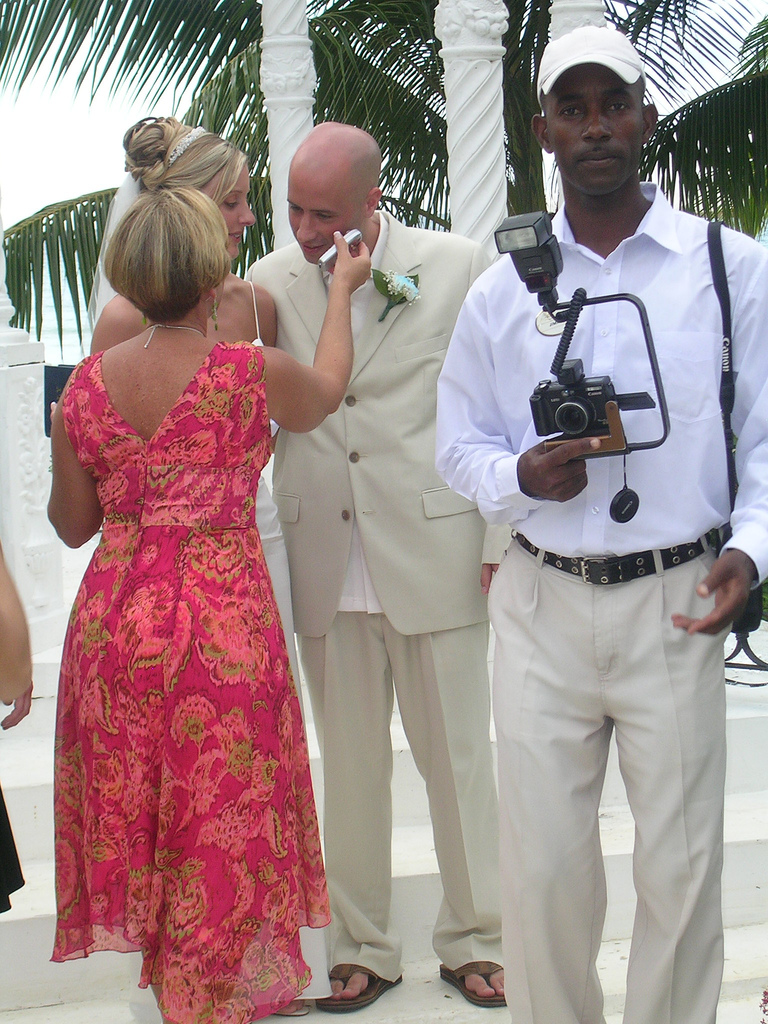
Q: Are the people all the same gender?
A: No, they are both male and female.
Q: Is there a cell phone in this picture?
A: Yes, there is a cell phone.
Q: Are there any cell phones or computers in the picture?
A: Yes, there is a cell phone.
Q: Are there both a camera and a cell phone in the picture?
A: Yes, there are both a cell phone and a camera.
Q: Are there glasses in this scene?
A: No, there are no glasses.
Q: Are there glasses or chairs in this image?
A: No, there are no glasses or chairs.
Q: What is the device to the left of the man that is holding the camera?
A: The device is a cell phone.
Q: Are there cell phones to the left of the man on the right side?
A: Yes, there is a cell phone to the left of the man.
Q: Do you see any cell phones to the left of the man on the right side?
A: Yes, there is a cell phone to the left of the man.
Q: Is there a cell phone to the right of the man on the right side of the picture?
A: No, the cell phone is to the left of the man.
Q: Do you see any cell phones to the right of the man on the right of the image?
A: No, the cell phone is to the left of the man.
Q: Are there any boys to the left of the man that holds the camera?
A: No, there is a cell phone to the left of the man.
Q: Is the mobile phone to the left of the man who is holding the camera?
A: Yes, the mobile phone is to the left of the man.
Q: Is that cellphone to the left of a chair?
A: No, the cellphone is to the left of the man.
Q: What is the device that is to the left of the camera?
A: The device is a cell phone.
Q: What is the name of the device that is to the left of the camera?
A: The device is a cell phone.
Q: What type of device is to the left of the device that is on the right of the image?
A: The device is a cell phone.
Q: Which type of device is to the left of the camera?
A: The device is a cell phone.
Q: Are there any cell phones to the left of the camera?
A: Yes, there is a cell phone to the left of the camera.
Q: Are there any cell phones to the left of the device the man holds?
A: Yes, there is a cell phone to the left of the camera.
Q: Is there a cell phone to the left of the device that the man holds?
A: Yes, there is a cell phone to the left of the camera.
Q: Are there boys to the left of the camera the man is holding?
A: No, there is a cell phone to the left of the camera.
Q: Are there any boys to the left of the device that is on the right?
A: No, there is a cell phone to the left of the camera.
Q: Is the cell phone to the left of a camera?
A: Yes, the cell phone is to the left of a camera.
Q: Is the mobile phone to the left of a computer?
A: No, the mobile phone is to the left of a camera.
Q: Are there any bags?
A: No, there are no bags.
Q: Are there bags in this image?
A: No, there are no bags.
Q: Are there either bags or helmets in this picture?
A: No, there are no bags or helmets.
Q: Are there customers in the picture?
A: No, there are no customers.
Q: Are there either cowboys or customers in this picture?
A: No, there are no customers or cowboys.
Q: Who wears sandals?
A: The man wears sandals.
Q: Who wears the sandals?
A: The man wears sandals.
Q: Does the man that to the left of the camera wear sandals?
A: Yes, the man wears sandals.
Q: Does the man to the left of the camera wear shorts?
A: No, the man wears sandals.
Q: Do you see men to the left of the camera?
A: Yes, there is a man to the left of the camera.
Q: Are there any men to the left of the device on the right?
A: Yes, there is a man to the left of the camera.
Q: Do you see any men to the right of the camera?
A: No, the man is to the left of the camera.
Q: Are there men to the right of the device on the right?
A: No, the man is to the left of the camera.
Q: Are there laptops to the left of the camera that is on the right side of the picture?
A: No, there is a man to the left of the camera.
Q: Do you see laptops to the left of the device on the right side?
A: No, there is a man to the left of the camera.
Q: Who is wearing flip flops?
A: The man is wearing flip flops.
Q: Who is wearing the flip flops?
A: The man is wearing flip flops.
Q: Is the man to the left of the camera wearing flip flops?
A: Yes, the man is wearing flip flops.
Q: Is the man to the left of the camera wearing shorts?
A: No, the man is wearing flip flops.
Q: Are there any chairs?
A: No, there are no chairs.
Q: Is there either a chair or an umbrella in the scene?
A: No, there are no chairs or umbrellas.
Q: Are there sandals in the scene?
A: Yes, there are sandals.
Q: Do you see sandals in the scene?
A: Yes, there are sandals.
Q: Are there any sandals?
A: Yes, there are sandals.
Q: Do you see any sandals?
A: Yes, there are sandals.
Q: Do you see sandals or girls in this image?
A: Yes, there are sandals.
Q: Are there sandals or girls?
A: Yes, there are sandals.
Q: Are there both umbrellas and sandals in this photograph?
A: No, there are sandals but no umbrellas.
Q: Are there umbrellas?
A: No, there are no umbrellas.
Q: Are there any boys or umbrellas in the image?
A: No, there are no umbrellas or boys.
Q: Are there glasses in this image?
A: No, there are no glasses.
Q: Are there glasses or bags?
A: No, there are no glasses or bags.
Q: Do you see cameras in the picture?
A: Yes, there is a camera.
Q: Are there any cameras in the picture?
A: Yes, there is a camera.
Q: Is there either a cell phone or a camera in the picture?
A: Yes, there is a camera.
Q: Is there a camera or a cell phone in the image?
A: Yes, there is a camera.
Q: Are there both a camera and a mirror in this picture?
A: No, there is a camera but no mirrors.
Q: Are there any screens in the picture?
A: No, there are no screens.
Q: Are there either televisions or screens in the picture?
A: No, there are no screens or televisions.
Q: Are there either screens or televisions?
A: No, there are no screens or televisions.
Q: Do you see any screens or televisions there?
A: No, there are no screens or televisions.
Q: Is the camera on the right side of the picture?
A: Yes, the camera is on the right of the image.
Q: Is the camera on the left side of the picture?
A: No, the camera is on the right of the image.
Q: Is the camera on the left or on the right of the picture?
A: The camera is on the right of the image.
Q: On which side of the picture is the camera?
A: The camera is on the right of the image.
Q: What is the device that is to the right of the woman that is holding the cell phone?
A: The device is a camera.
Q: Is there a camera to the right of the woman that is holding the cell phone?
A: Yes, there is a camera to the right of the woman.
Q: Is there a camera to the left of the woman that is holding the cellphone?
A: No, the camera is to the right of the woman.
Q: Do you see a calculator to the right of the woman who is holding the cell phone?
A: No, there is a camera to the right of the woman.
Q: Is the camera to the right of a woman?
A: Yes, the camera is to the right of a woman.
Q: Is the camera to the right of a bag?
A: No, the camera is to the right of a woman.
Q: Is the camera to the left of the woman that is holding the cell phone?
A: No, the camera is to the right of the woman.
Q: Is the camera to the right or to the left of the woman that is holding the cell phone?
A: The camera is to the right of the woman.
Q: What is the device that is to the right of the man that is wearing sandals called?
A: The device is a camera.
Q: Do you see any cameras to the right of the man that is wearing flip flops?
A: Yes, there is a camera to the right of the man.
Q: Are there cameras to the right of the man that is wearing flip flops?
A: Yes, there is a camera to the right of the man.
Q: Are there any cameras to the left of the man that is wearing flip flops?
A: No, the camera is to the right of the man.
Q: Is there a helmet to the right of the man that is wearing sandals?
A: No, there is a camera to the right of the man.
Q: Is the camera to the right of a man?
A: Yes, the camera is to the right of a man.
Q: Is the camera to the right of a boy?
A: No, the camera is to the right of a man.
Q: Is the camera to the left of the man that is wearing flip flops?
A: No, the camera is to the right of the man.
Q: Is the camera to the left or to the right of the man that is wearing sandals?
A: The camera is to the right of the man.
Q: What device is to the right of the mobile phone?
A: The device is a camera.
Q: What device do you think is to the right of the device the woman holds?
A: The device is a camera.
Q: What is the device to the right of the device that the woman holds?
A: The device is a camera.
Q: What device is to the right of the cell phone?
A: The device is a camera.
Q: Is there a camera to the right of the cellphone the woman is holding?
A: Yes, there is a camera to the right of the cell phone.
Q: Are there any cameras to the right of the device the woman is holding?
A: Yes, there is a camera to the right of the cell phone.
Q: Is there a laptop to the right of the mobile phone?
A: No, there is a camera to the right of the mobile phone.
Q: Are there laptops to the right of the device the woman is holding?
A: No, there is a camera to the right of the mobile phone.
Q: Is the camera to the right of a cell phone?
A: Yes, the camera is to the right of a cell phone.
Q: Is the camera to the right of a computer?
A: No, the camera is to the right of a cell phone.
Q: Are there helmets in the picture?
A: No, there are no helmets.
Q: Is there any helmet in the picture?
A: No, there are no helmets.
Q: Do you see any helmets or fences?
A: No, there are no helmets or fences.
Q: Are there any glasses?
A: No, there are no glasses.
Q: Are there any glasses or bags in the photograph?
A: No, there are no glasses or bags.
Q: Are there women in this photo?
A: Yes, there is a woman.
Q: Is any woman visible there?
A: Yes, there is a woman.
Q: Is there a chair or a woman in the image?
A: Yes, there is a woman.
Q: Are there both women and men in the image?
A: Yes, there are both a woman and a man.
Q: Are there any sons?
A: No, there are no sons.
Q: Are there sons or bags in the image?
A: No, there are no sons or bags.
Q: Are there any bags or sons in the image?
A: No, there are no sons or bags.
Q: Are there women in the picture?
A: Yes, there is a woman.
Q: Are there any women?
A: Yes, there is a woman.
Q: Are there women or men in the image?
A: Yes, there is a woman.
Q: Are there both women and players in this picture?
A: No, there is a woman but no players.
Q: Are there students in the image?
A: No, there are no students.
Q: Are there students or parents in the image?
A: No, there are no students or parents.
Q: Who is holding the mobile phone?
A: The woman is holding the mobile phone.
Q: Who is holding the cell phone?
A: The woman is holding the mobile phone.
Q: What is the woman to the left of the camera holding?
A: The woman is holding the mobile phone.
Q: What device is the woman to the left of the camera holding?
A: The woman is holding the cell phone.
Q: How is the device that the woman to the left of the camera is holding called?
A: The device is a cell phone.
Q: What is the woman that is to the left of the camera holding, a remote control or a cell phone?
A: The woman is holding a cell phone.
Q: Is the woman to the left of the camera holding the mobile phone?
A: Yes, the woman is holding the mobile phone.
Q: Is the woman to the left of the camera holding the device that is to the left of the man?
A: Yes, the woman is holding the mobile phone.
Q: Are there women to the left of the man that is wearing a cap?
A: Yes, there is a woman to the left of the man.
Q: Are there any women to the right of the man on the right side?
A: No, the woman is to the left of the man.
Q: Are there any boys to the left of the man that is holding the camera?
A: No, there is a woman to the left of the man.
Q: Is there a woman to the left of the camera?
A: Yes, there is a woman to the left of the camera.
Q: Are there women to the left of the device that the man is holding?
A: Yes, there is a woman to the left of the camera.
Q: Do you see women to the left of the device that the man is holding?
A: Yes, there is a woman to the left of the camera.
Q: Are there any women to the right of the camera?
A: No, the woman is to the left of the camera.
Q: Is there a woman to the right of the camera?
A: No, the woman is to the left of the camera.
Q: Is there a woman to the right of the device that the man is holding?
A: No, the woman is to the left of the camera.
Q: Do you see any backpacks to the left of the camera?
A: No, there is a woman to the left of the camera.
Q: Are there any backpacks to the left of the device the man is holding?
A: No, there is a woman to the left of the camera.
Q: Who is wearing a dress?
A: The woman is wearing a dress.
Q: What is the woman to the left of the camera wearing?
A: The woman is wearing a dress.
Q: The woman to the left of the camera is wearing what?
A: The woman is wearing a dress.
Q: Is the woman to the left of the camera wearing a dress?
A: Yes, the woman is wearing a dress.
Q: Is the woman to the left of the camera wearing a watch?
A: No, the woman is wearing a dress.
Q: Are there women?
A: Yes, there is a woman.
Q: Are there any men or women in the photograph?
A: Yes, there is a woman.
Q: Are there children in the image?
A: No, there are no children.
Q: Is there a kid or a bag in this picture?
A: No, there are no children or bags.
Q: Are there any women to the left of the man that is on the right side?
A: Yes, there is a woman to the left of the man.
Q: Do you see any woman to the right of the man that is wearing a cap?
A: No, the woman is to the left of the man.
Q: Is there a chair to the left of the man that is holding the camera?
A: No, there is a woman to the left of the man.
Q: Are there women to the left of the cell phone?
A: Yes, there is a woman to the left of the cell phone.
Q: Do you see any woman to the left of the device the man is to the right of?
A: Yes, there is a woman to the left of the cell phone.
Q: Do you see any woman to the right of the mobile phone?
A: No, the woman is to the left of the mobile phone.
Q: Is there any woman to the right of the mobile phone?
A: No, the woman is to the left of the mobile phone.